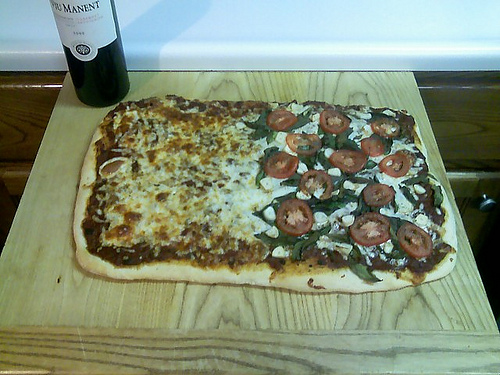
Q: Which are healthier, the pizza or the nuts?
A: The nuts are healthier than the pizza.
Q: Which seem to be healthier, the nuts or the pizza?
A: The nuts are healthier than the pizza.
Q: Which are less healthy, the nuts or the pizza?
A: The pizza are less healthy than the nuts.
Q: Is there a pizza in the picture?
A: Yes, there is a pizza.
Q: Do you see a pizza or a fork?
A: Yes, there is a pizza.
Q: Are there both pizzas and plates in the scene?
A: No, there is a pizza but no plates.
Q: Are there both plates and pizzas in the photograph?
A: No, there is a pizza but no plates.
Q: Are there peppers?
A: No, there are no peppers.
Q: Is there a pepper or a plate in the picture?
A: No, there are no peppers or plates.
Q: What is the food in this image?
A: The food is a pizza.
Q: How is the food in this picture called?
A: The food is a pizza.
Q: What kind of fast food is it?
A: The food is a pizza.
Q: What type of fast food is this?
A: This is a pizza.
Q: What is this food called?
A: This is a pizza.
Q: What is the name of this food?
A: This is a pizza.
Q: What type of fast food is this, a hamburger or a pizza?
A: This is a pizza.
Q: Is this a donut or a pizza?
A: This is a pizza.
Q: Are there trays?
A: No, there are no trays.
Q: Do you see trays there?
A: No, there are no trays.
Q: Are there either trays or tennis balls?
A: No, there are no trays or tennis balls.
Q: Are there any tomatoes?
A: Yes, there is a tomato.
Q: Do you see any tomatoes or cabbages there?
A: Yes, there is a tomato.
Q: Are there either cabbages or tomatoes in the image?
A: Yes, there is a tomato.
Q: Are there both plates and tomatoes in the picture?
A: No, there is a tomato but no plates.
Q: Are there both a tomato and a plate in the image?
A: No, there is a tomato but no plates.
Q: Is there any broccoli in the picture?
A: No, there is no broccoli.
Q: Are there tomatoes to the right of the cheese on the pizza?
A: Yes, there is a tomato to the right of the cheese.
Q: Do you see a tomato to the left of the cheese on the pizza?
A: No, the tomato is to the right of the cheese.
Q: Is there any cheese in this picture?
A: Yes, there is cheese.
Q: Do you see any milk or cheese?
A: Yes, there is cheese.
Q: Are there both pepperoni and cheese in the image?
A: No, there is cheese but no pepperoni.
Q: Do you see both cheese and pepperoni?
A: No, there is cheese but no pepperoni.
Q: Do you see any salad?
A: No, there is no salad.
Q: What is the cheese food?
A: The food is cheese.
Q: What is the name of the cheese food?
A: The food is cheese.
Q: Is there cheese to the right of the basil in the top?
A: No, the cheese is to the left of the basil.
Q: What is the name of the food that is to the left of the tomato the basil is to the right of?
A: The food is cheese.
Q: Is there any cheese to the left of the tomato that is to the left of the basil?
A: Yes, there is cheese to the left of the tomato.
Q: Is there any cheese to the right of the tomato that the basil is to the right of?
A: No, the cheese is to the left of the tomato.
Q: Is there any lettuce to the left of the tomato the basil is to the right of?
A: No, there is cheese to the left of the tomato.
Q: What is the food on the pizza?
A: The food is cheese.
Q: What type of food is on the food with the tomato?
A: The food is cheese.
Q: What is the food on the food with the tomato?
A: The food is cheese.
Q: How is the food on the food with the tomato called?
A: The food is cheese.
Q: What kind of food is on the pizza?
A: The food is cheese.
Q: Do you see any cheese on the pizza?
A: Yes, there is cheese on the pizza.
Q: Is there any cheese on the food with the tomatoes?
A: Yes, there is cheese on the pizza.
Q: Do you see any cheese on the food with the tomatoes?
A: Yes, there is cheese on the pizza.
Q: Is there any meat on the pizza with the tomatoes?
A: No, there is cheese on the pizza.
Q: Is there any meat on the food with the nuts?
A: No, there is cheese on the pizza.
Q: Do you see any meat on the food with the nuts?
A: No, there is cheese on the pizza.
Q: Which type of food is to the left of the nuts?
A: The food is cheese.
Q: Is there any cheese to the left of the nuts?
A: Yes, there is cheese to the left of the nuts.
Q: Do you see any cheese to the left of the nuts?
A: Yes, there is cheese to the left of the nuts.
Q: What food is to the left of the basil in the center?
A: The food is cheese.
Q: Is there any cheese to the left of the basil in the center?
A: Yes, there is cheese to the left of the basil.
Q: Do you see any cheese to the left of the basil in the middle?
A: Yes, there is cheese to the left of the basil.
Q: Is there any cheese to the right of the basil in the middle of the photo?
A: No, the cheese is to the left of the basil.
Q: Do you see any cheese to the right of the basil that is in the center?
A: No, the cheese is to the left of the basil.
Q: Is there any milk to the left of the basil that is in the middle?
A: No, there is cheese to the left of the basil.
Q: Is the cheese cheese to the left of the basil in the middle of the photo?
A: Yes, the cheese is to the left of the basil.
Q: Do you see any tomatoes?
A: Yes, there is a tomato.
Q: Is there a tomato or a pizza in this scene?
A: Yes, there is a tomato.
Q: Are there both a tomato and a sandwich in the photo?
A: No, there is a tomato but no sandwiches.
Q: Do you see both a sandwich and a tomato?
A: No, there is a tomato but no sandwiches.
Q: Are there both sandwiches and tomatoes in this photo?
A: No, there is a tomato but no sandwiches.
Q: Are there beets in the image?
A: No, there are no beets.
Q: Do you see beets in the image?
A: No, there are no beets.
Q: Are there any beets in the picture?
A: No, there are no beets.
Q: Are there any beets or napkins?
A: No, there are no beets or napkins.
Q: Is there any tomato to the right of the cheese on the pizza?
A: Yes, there is a tomato to the right of the cheese.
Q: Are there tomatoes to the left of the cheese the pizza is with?
A: No, the tomato is to the right of the cheese.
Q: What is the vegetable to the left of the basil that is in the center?
A: The vegetable is a tomato.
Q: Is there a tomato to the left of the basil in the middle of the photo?
A: Yes, there is a tomato to the left of the basil.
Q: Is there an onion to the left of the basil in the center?
A: No, there is a tomato to the left of the basil.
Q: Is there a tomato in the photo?
A: Yes, there is a tomato.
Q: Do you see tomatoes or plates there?
A: Yes, there is a tomato.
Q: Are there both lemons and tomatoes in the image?
A: No, there is a tomato but no lemons.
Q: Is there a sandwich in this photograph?
A: No, there are no sandwiches.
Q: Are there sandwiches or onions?
A: No, there are no sandwiches or onions.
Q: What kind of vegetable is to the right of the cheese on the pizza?
A: The vegetable is a tomato.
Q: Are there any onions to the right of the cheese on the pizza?
A: No, there is a tomato to the right of the cheese.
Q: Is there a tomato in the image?
A: Yes, there is a tomato.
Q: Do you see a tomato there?
A: Yes, there is a tomato.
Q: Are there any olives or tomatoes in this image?
A: Yes, there is a tomato.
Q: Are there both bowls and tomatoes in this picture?
A: No, there is a tomato but no bowls.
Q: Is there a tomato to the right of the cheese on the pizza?
A: Yes, there is a tomato to the right of the cheese.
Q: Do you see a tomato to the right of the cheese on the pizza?
A: Yes, there is a tomato to the right of the cheese.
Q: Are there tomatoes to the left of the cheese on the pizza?
A: No, the tomato is to the right of the cheese.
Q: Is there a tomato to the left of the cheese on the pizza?
A: No, the tomato is to the right of the cheese.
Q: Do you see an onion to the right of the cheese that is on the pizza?
A: No, there is a tomato to the right of the cheese.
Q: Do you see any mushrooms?
A: No, there are no mushrooms.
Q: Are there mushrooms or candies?
A: No, there are no mushrooms or candies.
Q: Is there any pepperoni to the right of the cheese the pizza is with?
A: No, there is basil to the right of the cheese.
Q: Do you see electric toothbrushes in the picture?
A: No, there are no electric toothbrushes.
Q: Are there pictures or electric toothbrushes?
A: No, there are no electric toothbrushes or pictures.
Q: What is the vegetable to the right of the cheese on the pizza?
A: The vegetable is basil.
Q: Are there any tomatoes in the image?
A: Yes, there is a tomato.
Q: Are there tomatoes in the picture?
A: Yes, there is a tomato.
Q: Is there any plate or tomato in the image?
A: Yes, there is a tomato.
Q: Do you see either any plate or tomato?
A: Yes, there is a tomato.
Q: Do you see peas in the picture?
A: No, there are no peas.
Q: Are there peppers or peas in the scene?
A: No, there are no peas or peppers.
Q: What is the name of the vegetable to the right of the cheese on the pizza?
A: The vegetable is a tomato.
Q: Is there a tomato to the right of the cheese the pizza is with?
A: Yes, there is a tomato to the right of the cheese.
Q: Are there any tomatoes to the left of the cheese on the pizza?
A: No, the tomato is to the right of the cheese.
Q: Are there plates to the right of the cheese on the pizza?
A: No, there is a tomato to the right of the cheese.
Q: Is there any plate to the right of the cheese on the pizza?
A: No, there is a tomato to the right of the cheese.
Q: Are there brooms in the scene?
A: No, there are no brooms.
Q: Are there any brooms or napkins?
A: No, there are no brooms or napkins.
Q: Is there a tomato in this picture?
A: Yes, there is a tomato.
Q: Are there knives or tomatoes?
A: Yes, there is a tomato.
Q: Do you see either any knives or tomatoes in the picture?
A: Yes, there is a tomato.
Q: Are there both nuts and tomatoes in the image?
A: Yes, there are both a tomato and nuts.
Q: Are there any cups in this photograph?
A: No, there are no cups.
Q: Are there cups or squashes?
A: No, there are no cups or squashes.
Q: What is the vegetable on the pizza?
A: The vegetable is a tomato.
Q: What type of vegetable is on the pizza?
A: The vegetable is a tomato.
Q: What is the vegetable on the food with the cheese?
A: The vegetable is a tomato.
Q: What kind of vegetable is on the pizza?
A: The vegetable is a tomato.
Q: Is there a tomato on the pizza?
A: Yes, there is a tomato on the pizza.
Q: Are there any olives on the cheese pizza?
A: No, there is a tomato on the pizza.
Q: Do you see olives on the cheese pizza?
A: No, there is a tomato on the pizza.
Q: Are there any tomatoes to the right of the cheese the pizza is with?
A: Yes, there is a tomato to the right of the cheese.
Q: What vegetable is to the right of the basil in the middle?
A: The vegetable is a tomato.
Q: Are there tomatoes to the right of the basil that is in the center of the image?
A: Yes, there is a tomato to the right of the basil.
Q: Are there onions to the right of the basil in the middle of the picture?
A: No, there is a tomato to the right of the basil.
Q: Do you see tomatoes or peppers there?
A: Yes, there are tomatoes.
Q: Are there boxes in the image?
A: No, there are no boxes.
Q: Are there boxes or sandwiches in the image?
A: No, there are no boxes or sandwiches.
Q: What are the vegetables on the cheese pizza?
A: The vegetables are tomatoes.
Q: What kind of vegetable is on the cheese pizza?
A: The vegetables are tomatoes.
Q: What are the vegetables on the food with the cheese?
A: The vegetables are tomatoes.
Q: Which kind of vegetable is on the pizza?
A: The vegetables are tomatoes.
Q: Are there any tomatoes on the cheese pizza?
A: Yes, there are tomatoes on the pizza.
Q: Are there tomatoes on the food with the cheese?
A: Yes, there are tomatoes on the pizza.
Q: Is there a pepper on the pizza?
A: No, there are tomatoes on the pizza.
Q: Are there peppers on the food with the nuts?
A: No, there are tomatoes on the pizza.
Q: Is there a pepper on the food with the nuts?
A: No, there are tomatoes on the pizza.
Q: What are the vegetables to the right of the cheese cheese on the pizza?
A: The vegetables are tomatoes.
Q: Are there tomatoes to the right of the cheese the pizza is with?
A: Yes, there are tomatoes to the right of the cheese.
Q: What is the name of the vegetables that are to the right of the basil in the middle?
A: The vegetables are tomatoes.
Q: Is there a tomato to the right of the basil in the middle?
A: Yes, there are tomatoes to the right of the basil.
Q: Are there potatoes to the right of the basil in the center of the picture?
A: No, there are tomatoes to the right of the basil.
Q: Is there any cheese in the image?
A: Yes, there is cheese.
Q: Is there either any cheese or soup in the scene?
A: Yes, there is cheese.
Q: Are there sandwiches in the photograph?
A: No, there are no sandwiches.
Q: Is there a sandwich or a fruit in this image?
A: No, there are no sandwiches or fruits.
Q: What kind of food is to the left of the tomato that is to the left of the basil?
A: The food is cheese.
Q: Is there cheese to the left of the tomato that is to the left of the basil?
A: Yes, there is cheese to the left of the tomato.